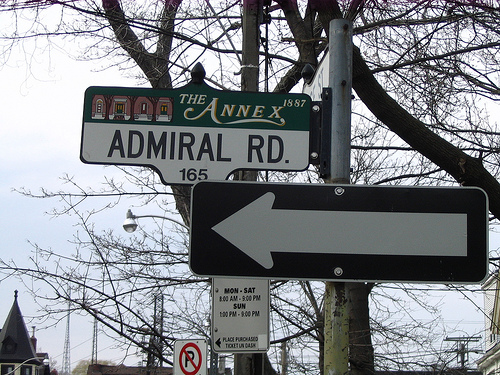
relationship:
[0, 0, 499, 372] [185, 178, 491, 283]
branches behind black sign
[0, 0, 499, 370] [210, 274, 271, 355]
branches behind sign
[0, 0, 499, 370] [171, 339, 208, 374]
branches behind no parking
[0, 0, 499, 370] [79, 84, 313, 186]
branches behind street sign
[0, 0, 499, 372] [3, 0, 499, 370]
branches on trees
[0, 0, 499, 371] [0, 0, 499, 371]
clouds in skies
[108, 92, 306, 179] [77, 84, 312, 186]
text on road signage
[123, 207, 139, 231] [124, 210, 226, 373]
lamp on street light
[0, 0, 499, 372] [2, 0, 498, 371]
branches on tree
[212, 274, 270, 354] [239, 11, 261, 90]
sign on metal pole with sign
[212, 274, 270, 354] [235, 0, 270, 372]
sign on pole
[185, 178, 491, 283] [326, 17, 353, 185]
black sign on gray metal pole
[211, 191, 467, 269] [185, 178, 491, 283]
arrow on black sign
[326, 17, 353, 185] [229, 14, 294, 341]
gray metal pole hanging from pole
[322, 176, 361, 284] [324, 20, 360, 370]
street sign bolted bolted to pole